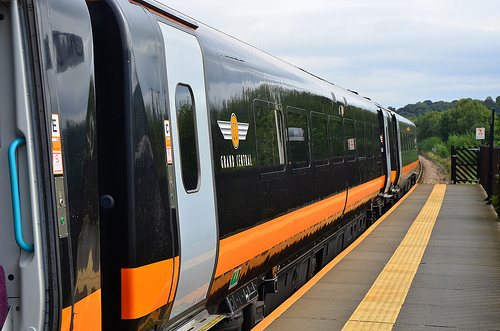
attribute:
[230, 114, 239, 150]
circle — orange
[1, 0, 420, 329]
train — sitting, stopped, black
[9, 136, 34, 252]
handle — blue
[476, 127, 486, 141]
sign — white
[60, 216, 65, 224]
button — green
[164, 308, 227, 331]
step — silver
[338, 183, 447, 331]
stripe — yellow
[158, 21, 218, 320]
door — silver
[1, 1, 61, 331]
door — open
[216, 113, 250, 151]
logo — orange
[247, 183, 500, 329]
loading area — concrete, floor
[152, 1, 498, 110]
sky — cloudy, blue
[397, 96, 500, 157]
wooded area — lush, distant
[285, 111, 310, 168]
window — dark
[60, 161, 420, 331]
stripe — orange